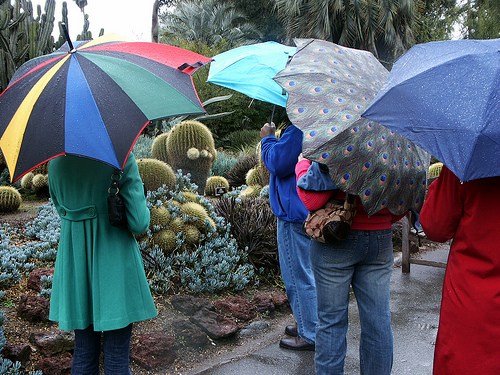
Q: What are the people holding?
A: Umbrellas.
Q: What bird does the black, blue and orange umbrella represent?
A: Peacock.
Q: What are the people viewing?
A: Cacti.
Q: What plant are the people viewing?
A: Cacti.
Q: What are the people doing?
A: Viewing plants.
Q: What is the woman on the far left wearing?
A: Teal coat.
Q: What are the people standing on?
A: Sidewalk.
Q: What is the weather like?
A: Raining.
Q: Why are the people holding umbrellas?
A: Keep dry.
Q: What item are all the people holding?
A: Umbrellas.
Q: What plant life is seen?
A: Cactus.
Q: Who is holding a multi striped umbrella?
A: Woman with green coat.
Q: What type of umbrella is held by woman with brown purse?
A: Peacock print.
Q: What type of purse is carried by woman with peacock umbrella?
A: Coach.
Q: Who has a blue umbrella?
A: Person with long red coat.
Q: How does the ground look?
A: Wet.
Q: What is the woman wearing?
A: A green coat.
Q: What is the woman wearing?
A: A red coat.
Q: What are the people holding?
A: Umbrellas.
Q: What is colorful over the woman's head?
A: An umbrella.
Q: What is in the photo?
A: A group of people.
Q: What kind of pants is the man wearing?
A: Jeans.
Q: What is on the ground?
A: Cactus plant.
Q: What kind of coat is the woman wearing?
A: Trenchcoat.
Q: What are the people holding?
A: Umbrellas.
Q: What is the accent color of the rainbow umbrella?
A: Black.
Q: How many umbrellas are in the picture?
A: Four.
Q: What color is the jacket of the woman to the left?
A: Green.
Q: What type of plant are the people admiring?
A: Catus.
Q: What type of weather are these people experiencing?
A: Rain.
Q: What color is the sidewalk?
A: Grey.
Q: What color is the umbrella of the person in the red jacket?
A: Blue.